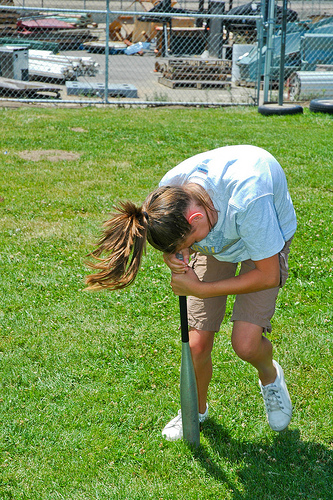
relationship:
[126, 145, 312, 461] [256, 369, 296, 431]
woman wearing shoe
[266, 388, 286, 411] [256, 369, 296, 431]
shoestring on shoe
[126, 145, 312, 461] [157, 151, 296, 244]
woman wears shirt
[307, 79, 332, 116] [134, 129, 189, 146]
tire on grass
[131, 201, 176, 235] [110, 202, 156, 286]
rubber band in hair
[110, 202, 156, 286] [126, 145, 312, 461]
hair of woman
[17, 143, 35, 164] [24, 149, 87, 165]
patch of dirt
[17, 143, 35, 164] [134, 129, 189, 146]
patch in grass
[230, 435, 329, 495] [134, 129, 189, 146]
shadow on grass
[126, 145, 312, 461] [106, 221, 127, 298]
woman has ponytail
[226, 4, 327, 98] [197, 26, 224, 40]
trash behind fence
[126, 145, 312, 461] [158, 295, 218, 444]
woman holding baseball bat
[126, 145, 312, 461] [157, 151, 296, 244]
woman wearing shirt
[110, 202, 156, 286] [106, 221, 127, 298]
hair in ponytail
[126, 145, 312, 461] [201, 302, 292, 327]
woman in brown shorts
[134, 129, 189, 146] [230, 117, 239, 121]
grass on ground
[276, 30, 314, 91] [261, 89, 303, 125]
pole in tire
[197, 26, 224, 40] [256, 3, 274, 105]
fence has gate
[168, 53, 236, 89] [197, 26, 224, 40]
pallets behind fence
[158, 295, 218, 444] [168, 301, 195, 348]
baseball bat has handle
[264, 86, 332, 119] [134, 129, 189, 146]
tires on grass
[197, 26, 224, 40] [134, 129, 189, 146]
fence behind grass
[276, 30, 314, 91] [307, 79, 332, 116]
pole in tire